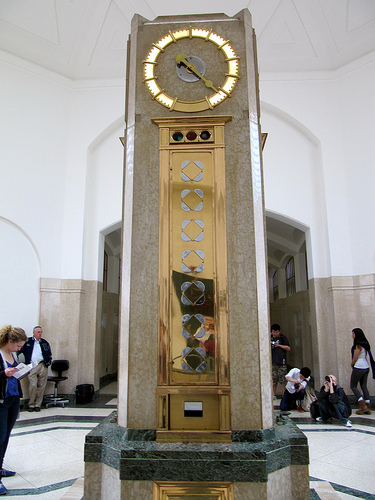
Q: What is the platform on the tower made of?
A: Stones.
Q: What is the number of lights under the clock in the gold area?
A: 3.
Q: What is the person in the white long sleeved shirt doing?
A: Kneeling on floor.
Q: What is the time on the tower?
A: 10:22.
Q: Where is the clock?
A: Museum.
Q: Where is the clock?
A: Tower.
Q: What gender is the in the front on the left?
A: Female.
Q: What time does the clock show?
A: 10:26.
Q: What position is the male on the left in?
A: Standing.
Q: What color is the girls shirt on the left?
A: Blue.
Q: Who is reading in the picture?
A: Girl on the left.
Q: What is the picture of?
A: A clock.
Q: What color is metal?
A: Bronze.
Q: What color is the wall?
A: White.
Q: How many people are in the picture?
A: Six.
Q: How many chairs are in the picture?
A: One.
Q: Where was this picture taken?
A: In a museum.